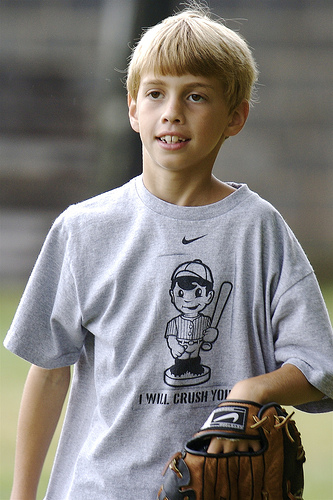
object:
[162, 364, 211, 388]
base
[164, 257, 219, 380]
child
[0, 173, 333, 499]
shirt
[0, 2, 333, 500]
young boy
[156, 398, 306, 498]
baseball glove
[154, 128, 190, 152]
mouth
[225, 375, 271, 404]
wrist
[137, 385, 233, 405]
text